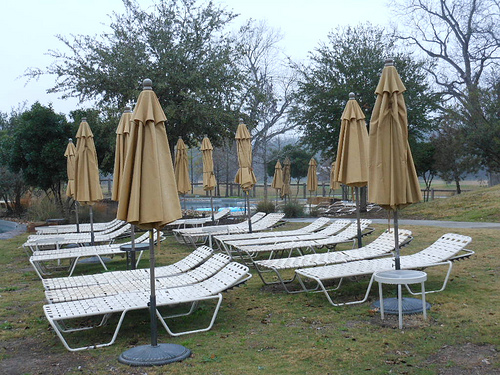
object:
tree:
[385, 0, 500, 187]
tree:
[282, 17, 441, 197]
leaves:
[49, 17, 258, 129]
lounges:
[23, 207, 475, 351]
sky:
[0, 0, 497, 136]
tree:
[8, 0, 262, 155]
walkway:
[226, 216, 499, 229]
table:
[368, 269, 428, 330]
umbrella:
[115, 77, 183, 228]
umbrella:
[333, 91, 369, 187]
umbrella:
[234, 117, 256, 190]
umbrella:
[74, 115, 104, 202]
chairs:
[294, 232, 476, 307]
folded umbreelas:
[64, 58, 423, 258]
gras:
[0, 317, 500, 375]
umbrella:
[72, 116, 103, 206]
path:
[238, 216, 500, 234]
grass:
[0, 182, 498, 371]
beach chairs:
[35, 261, 253, 352]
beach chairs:
[253, 226, 414, 295]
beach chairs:
[230, 218, 373, 270]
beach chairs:
[29, 229, 166, 279]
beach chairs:
[180, 211, 286, 250]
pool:
[190, 205, 286, 218]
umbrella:
[364, 58, 421, 215]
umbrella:
[229, 115, 258, 193]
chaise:
[289, 231, 478, 313]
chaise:
[251, 227, 414, 305]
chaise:
[40, 261, 250, 354]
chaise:
[178, 211, 287, 250]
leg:
[43, 310, 129, 352]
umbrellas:
[199, 135, 218, 191]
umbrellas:
[306, 155, 317, 189]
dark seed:
[261, 318, 268, 324]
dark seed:
[349, 334, 358, 342]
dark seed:
[382, 354, 413, 368]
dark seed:
[246, 308, 253, 312]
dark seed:
[22, 325, 30, 330]